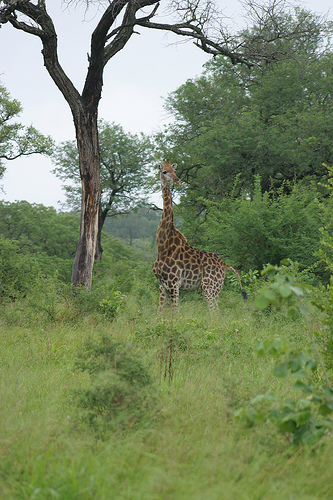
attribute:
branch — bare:
[135, 17, 256, 69]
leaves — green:
[176, 10, 328, 191]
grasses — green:
[20, 345, 182, 452]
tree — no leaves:
[2, 2, 241, 293]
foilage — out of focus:
[71, 323, 193, 428]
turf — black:
[238, 287, 248, 299]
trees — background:
[2, 2, 330, 314]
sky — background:
[0, 2, 333, 207]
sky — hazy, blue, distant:
[8, 146, 110, 189]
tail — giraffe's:
[225, 260, 251, 304]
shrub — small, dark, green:
[68, 331, 161, 448]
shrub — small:
[252, 274, 303, 312]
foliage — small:
[36, 225, 199, 328]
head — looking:
[155, 156, 183, 190]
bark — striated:
[75, 183, 107, 305]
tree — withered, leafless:
[1, 1, 321, 292]